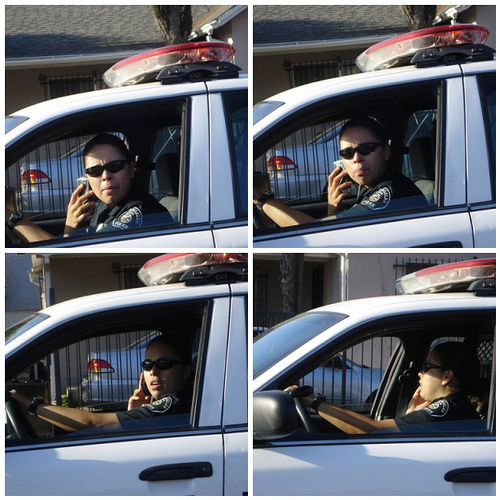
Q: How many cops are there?
A: One.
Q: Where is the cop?
A: In a car.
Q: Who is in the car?
A: A cop.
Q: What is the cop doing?
A: Talking.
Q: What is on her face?
A: Sunglasses.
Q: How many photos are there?
A: Four.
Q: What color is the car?
A: White.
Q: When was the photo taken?
A: Daytime.